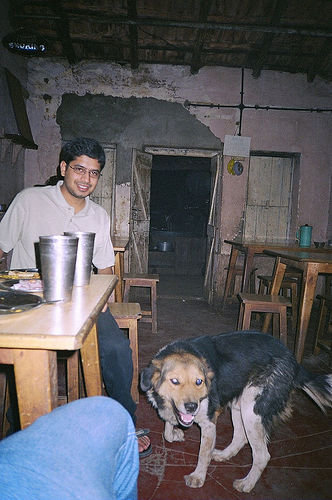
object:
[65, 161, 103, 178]
glasses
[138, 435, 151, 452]
toes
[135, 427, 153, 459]
sandal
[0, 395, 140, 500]
trouser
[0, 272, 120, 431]
table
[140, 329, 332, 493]
dog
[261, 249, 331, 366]
table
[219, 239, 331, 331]
table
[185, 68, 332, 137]
black piping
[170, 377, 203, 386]
yellow eyes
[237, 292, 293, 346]
stool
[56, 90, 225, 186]
paint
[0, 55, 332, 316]
wall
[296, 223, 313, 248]
pitcher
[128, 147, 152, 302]
door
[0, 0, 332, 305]
building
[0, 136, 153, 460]
man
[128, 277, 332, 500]
floor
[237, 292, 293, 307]
seat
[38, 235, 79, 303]
cup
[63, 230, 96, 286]
cup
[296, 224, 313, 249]
container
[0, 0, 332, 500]
restaurant